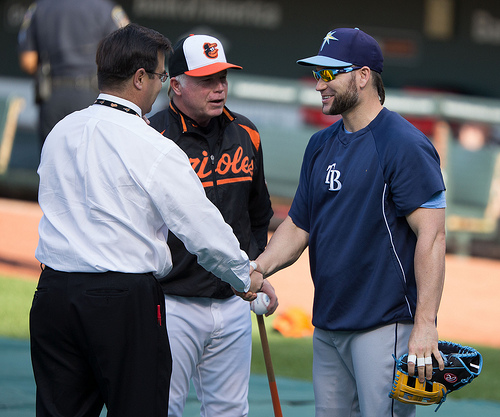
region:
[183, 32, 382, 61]
these are two caps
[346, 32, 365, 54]
the cap is blue in color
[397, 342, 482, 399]
this is a baseball glove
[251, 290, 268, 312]
this is a baseball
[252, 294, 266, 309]
the ball is white in color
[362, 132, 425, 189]
the t-shirt is blue in color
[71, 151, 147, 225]
the shirt is white in color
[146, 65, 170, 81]
this is a pair of spectacles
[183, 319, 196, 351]
the trouser is white in color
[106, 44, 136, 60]
the hair is black in color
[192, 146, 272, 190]
orioles is on jacket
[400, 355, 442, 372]
fingers are bandaged on hand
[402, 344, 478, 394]
the mitt is blue and black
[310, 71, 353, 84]
player is wearing sunglasses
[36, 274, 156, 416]
the man has black pants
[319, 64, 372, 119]
the man is smiling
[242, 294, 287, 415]
man holding a bat and ball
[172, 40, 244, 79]
the mans hat is orange and black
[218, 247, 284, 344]
two men are shaking hands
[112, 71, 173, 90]
the man wearing glasses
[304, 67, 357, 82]
blue and yellow sunglasses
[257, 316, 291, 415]
brown baseball handle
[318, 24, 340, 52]
design on baseball cap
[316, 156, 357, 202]
team logo on front of shirt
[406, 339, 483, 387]
black baseball glove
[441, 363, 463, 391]
logo on side of baseball glove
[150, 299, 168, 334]
red ink pen in pocket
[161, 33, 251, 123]
man in black and orange cap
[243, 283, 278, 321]
white baseball in hand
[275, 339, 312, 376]
grass on baseball field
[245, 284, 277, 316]
Baseball being held by man.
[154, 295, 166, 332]
Red pen cap in man's pocket.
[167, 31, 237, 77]
Orange, white and black hat.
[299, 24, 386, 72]
Sky blue and navy blue baseball cap.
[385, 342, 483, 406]
Blue and yellow baseball glove.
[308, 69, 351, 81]
Blue and yellow sunglasses being worn by player.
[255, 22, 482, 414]
Baseball player shaking mans hand.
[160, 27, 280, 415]
Man in orange and black standing between two people.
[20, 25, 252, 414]
Man shaking hands with baseball player.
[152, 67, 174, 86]
Glasses being worn by man in black pants.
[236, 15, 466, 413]
man wearing blue shirt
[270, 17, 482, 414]
man wearing reflective sunglasses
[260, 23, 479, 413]
man wearing blue baseball cap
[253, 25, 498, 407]
man holding blue and black catcher's mitt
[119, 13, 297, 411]
man wearing orange and black jacket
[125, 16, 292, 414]
man wearing orange black and white hat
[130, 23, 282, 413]
older man wearing white pants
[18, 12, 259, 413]
man wearing black slacks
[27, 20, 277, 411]
man holding small white baseball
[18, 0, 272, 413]
man wearing eyeglasses